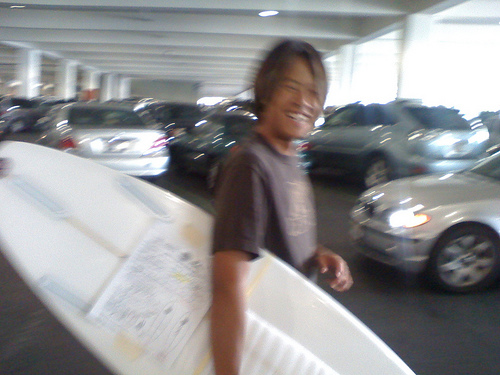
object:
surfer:
[211, 37, 356, 375]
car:
[349, 146, 498, 296]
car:
[307, 102, 491, 193]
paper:
[87, 216, 215, 372]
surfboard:
[1, 139, 418, 375]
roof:
[2, 2, 460, 99]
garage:
[1, 2, 498, 375]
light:
[257, 6, 280, 20]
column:
[15, 48, 40, 102]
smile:
[283, 108, 313, 122]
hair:
[253, 39, 330, 113]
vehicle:
[172, 107, 314, 194]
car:
[0, 102, 172, 178]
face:
[270, 58, 319, 137]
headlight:
[387, 204, 433, 231]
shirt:
[207, 130, 321, 285]